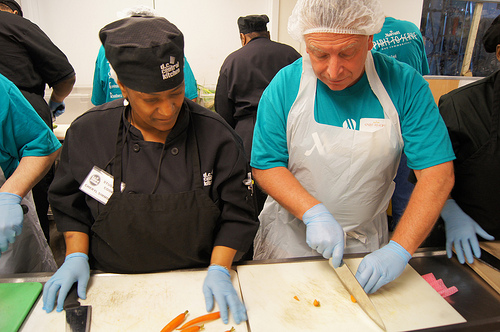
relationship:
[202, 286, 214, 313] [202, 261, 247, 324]
finger on glove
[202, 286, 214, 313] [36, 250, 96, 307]
finger on glove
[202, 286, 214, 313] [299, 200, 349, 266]
finger on glove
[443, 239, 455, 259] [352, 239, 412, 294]
finger on glove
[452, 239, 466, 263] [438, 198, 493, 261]
finger on glove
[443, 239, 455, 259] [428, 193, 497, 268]
finger on glove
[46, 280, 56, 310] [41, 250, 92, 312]
finger on glove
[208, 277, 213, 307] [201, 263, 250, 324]
finger on glove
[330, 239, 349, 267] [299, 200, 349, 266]
finger on glove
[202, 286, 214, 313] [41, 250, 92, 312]
finger on glove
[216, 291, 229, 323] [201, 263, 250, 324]
finger on glove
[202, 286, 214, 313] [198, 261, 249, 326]
finger on glove